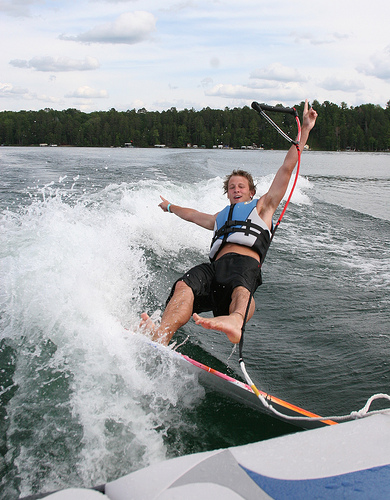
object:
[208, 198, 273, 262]
jacket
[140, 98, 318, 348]
man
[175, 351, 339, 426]
board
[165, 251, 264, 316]
shorts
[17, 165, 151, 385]
water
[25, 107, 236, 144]
trees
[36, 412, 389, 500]
boat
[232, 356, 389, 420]
rope